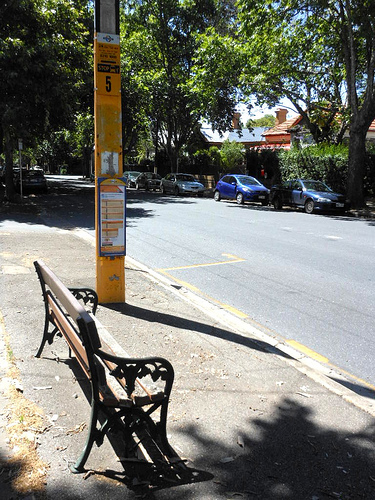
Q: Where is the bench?
A: Sidewalk.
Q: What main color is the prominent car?
A: Blue.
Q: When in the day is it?
A: Afternoon.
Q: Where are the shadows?
A: Ground.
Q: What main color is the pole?
A: Yellow.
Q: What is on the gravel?
A: Brown bench.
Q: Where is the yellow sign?
A: On a sidewalk.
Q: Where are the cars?
A: Parked on the street.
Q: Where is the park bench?
A: On sidewalk.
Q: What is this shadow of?
A: The pole.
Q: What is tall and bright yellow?
A: The pole.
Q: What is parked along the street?
A: Cars.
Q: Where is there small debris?
A: On sidewalk next to bench.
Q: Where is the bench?
A: Sidewalk.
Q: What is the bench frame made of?
A: Iron.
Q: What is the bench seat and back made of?
A: Wood.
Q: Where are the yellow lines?
A: Street.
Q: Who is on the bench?
A: No one.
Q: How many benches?
A: 1.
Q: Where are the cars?
A: Parked.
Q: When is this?
A: Noon.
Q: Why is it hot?
A: Summer.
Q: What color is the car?
A: Blue.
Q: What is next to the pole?
A: Bench.